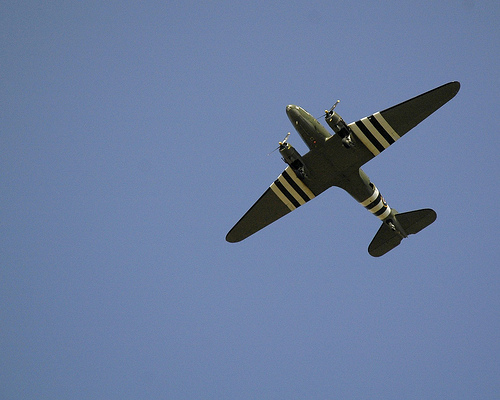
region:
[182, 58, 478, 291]
plane in the sky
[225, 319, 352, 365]
the sky is clear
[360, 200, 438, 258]
tail of the plane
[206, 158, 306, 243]
wing of the plane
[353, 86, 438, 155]
wing of the plane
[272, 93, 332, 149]
front of the plane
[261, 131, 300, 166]
engine of the plane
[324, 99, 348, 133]
engine on the plane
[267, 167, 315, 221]
stripes on the plane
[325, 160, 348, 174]
the plane is green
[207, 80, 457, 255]
plane is in the air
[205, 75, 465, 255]
white stripes on plane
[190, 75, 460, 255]
black stripes on plane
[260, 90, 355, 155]
plane has 2 propellers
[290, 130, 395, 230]
plane's wheels are out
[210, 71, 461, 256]
the plane is green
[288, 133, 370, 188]
plane wheels are black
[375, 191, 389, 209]
circular shape on plane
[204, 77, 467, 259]
picture taken below the plane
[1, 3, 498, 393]
the sky is clear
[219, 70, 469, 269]
one plane in sky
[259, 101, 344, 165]
plane has two propellers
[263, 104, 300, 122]
plane has grey nose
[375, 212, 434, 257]
plane has grey tail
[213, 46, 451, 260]
plane has grey wings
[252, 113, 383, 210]
white stripes on wings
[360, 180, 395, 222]
white stripes near tail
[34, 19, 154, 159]
blue and clear sky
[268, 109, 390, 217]
three stripes on each side of wings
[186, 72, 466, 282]
An old green plane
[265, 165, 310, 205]
Black and white stripes on left wing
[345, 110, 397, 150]
Black and white stripes on right wing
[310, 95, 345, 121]
The left engine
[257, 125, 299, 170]
The right engine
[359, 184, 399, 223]
Black and white stripe on tail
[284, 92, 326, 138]
Cockpit at front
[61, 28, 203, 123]
Blue sky around plane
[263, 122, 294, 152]
Left propeller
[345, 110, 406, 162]
Three white stripes on the underside of the plane wing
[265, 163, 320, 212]
Three white stripes on the underside of the plane wing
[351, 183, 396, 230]
Three white stripes on the body of the plane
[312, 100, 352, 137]
Front right engine of the plane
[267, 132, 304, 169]
Front left engine of the plane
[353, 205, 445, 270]
Two-sided tail of the plane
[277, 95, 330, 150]
Front of the plane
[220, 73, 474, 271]
Green and white plane flying through the sky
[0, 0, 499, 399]
Medium blue sky with a plane flying through it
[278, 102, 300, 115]
Nose of the plane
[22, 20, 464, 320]
this is an outdoor setting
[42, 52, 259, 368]
this is the open sky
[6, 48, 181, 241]
the sky is very clear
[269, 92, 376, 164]
the plane has two propellers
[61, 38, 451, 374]
this is an airplane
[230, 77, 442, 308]
the plane is flying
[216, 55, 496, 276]
the plane is small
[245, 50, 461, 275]
the plane is white and green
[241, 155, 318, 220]
these are stripes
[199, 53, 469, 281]
black plane in blue sky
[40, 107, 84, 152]
blue sky with no clouds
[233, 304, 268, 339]
blue sky with no clouds